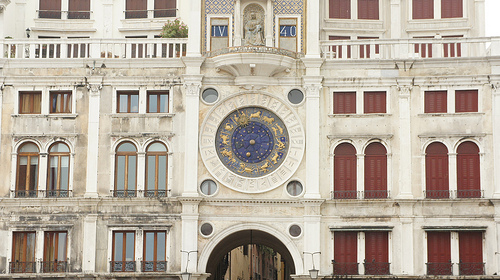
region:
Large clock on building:
[198, 89, 305, 195]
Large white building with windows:
[0, 0, 499, 279]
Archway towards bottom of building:
[192, 222, 303, 278]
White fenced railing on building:
[0, 38, 196, 66]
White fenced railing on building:
[318, 38, 498, 60]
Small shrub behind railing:
[155, 16, 187, 54]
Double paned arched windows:
[109, 136, 171, 202]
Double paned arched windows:
[11, 136, 71, 199]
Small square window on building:
[114, 89, 142, 114]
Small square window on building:
[145, 87, 173, 116]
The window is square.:
[10, 85, 48, 118]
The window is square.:
[45, 83, 78, 122]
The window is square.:
[113, 85, 142, 119]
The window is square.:
[143, 83, 173, 115]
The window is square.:
[331, 82, 360, 119]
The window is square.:
[358, 87, 390, 116]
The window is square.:
[421, 83, 452, 120]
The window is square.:
[451, 79, 492, 115]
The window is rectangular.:
[358, 225, 393, 278]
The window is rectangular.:
[326, 221, 363, 278]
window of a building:
[115, 93, 146, 120]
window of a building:
[111, 142, 138, 161]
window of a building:
[143, 128, 165, 154]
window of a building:
[104, 158, 142, 199]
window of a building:
[105, 225, 151, 269]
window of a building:
[128, 212, 191, 274]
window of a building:
[32, 223, 83, 278]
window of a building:
[4, 133, 48, 195]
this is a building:
[22, 28, 451, 269]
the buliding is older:
[31, 18, 439, 254]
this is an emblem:
[198, 93, 309, 172]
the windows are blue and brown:
[86, 113, 165, 254]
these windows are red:
[338, 125, 498, 247]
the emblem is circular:
[142, 35, 372, 247]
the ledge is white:
[24, 14, 219, 106]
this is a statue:
[250, 15, 320, 91]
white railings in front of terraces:
[6, 5, 191, 57]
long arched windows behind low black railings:
[10, 133, 180, 205]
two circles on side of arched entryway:
[182, 205, 319, 278]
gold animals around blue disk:
[196, 81, 313, 197]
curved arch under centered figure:
[199, 0, 309, 87]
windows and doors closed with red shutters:
[328, 86, 489, 275]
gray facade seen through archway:
[201, 225, 300, 276]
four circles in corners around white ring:
[198, 85, 310, 198]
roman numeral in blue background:
[208, 20, 231, 42]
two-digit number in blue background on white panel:
[275, 10, 296, 51]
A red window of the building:
[324, 140, 361, 209]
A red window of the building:
[417, 134, 457, 199]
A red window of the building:
[418, 219, 465, 276]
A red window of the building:
[453, 225, 491, 277]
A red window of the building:
[362, 85, 388, 122]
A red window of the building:
[427, 94, 442, 116]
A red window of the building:
[455, 80, 477, 119]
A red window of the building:
[331, 4, 360, 29]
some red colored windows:
[321, 133, 401, 213]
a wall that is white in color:
[377, 103, 418, 190]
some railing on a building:
[317, 33, 498, 67]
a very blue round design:
[232, 113, 274, 163]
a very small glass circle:
[194, 89, 226, 104]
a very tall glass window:
[101, 222, 138, 269]